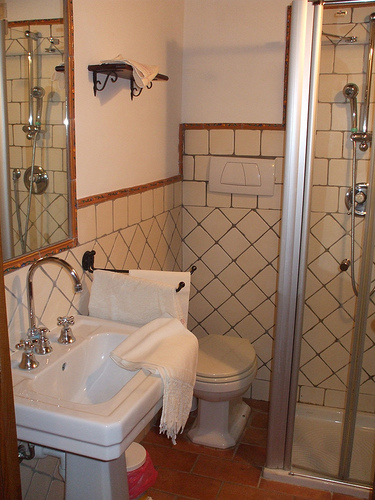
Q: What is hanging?
A: A towel.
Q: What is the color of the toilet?
A: White.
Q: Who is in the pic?
A: No one.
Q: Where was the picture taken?
A: Bathroom.